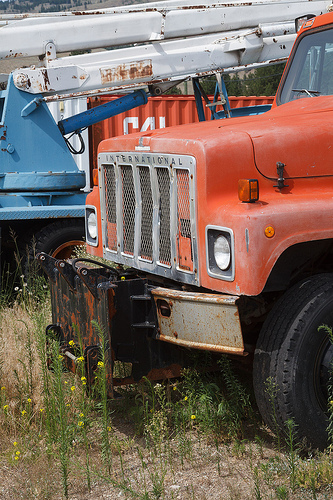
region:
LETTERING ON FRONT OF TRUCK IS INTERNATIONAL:
[107, 149, 202, 176]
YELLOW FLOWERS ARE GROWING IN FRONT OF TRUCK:
[6, 342, 118, 483]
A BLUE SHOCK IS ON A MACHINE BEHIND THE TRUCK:
[44, 82, 158, 143]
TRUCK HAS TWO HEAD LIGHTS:
[84, 200, 237, 285]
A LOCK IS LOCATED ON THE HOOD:
[271, 158, 288, 190]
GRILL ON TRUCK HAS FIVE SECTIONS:
[93, 150, 205, 284]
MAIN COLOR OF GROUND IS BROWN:
[19, 404, 250, 479]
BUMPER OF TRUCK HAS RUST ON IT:
[156, 284, 253, 358]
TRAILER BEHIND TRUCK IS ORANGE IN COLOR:
[93, 97, 283, 140]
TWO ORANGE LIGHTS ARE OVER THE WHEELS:
[92, 164, 262, 204]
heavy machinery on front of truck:
[34, 251, 154, 403]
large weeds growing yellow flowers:
[5, 336, 208, 492]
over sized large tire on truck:
[253, 268, 331, 448]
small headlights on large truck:
[85, 203, 232, 276]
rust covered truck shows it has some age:
[147, 285, 246, 353]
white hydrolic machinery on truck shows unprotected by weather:
[1, 0, 331, 70]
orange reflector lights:
[236, 178, 260, 202]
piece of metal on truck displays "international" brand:
[95, 150, 201, 287]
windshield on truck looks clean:
[274, 25, 332, 103]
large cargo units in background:
[42, 93, 276, 190]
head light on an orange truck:
[207, 222, 237, 282]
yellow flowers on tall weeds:
[38, 323, 130, 442]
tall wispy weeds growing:
[43, 334, 150, 471]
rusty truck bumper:
[148, 282, 258, 363]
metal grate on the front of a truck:
[98, 150, 202, 291]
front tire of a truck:
[238, 278, 328, 463]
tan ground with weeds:
[131, 428, 217, 492]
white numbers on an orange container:
[118, 107, 166, 138]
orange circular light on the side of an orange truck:
[260, 221, 277, 241]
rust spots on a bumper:
[163, 297, 241, 347]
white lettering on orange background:
[117, 116, 170, 142]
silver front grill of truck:
[97, 150, 200, 277]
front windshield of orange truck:
[278, 29, 331, 80]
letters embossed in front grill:
[102, 151, 182, 167]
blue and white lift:
[1, 2, 324, 238]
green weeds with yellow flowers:
[20, 267, 308, 490]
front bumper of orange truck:
[135, 281, 249, 349]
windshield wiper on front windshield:
[289, 83, 318, 97]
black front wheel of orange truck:
[256, 268, 331, 442]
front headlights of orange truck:
[84, 212, 230, 271]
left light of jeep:
[207, 226, 257, 284]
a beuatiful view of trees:
[12, 329, 322, 485]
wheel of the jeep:
[243, 286, 331, 455]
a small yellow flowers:
[61, 336, 92, 363]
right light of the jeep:
[84, 209, 117, 252]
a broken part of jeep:
[83, 266, 257, 343]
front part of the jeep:
[50, 248, 194, 333]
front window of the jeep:
[99, 165, 223, 280]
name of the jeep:
[104, 151, 195, 177]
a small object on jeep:
[230, 170, 271, 208]